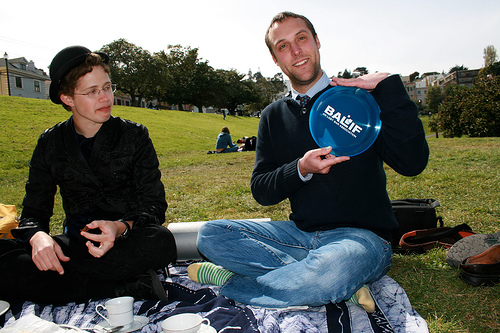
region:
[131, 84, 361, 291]
the grass is green and visible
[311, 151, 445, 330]
the grass is green and visible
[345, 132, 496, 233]
the grass is green and visible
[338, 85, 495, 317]
the grass is green and visible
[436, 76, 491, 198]
the grass is green and visible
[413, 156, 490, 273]
the grass is green and visible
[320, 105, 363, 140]
writing on the frisbee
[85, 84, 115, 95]
eyeglasses on the person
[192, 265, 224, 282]
green and yellow striped sock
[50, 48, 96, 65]
part of black hat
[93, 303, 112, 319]
handle on the mug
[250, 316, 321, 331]
part of the blanket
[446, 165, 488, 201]
an area of grass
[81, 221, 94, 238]
person holding something with fingers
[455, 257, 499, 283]
part of black shoe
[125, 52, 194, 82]
leaves on tree branches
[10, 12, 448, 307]
Two people having a picnic.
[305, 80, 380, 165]
A blue frisbee with writing on it.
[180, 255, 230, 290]
Striped socks.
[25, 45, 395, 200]
The person is looking at the frisbee.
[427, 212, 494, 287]
Shoes.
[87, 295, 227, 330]
Tea cups and saucers.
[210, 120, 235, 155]
A woman wearing a blue hoodie.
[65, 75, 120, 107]
The person is wearing glasses.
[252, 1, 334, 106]
The man is smiling.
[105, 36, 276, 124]
A row of trees.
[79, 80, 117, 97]
The eyeglasses the man is wearing.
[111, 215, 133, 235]
The black watch on the man's wrist.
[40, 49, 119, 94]
The black hat on the man's head.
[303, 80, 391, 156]
The Frisbee in the man's hand.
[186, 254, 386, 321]
The green and yellow socks the man is wearing.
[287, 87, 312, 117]
The tie the man is wearing.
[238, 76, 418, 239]
The dark blue sweater the man is wearing.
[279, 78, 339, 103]
The dress shirt under the blue sweater the man is wearing.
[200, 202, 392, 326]
The blue jeans the man is wearing.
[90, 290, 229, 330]
The two white tea cups on the blanket.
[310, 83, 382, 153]
blue and white frisbee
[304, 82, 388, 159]
a blue and white frisbee with a name on it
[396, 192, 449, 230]
a cooler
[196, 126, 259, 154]
people in background sitting on grass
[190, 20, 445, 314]
man holding frisbee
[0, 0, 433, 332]
two people sitting down on a blanket on grass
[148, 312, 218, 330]
a white tea cup and saucer on blanket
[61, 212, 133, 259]
a person wearing a watch on arm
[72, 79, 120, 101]
a person wearing glasses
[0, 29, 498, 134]
a house and trees in background